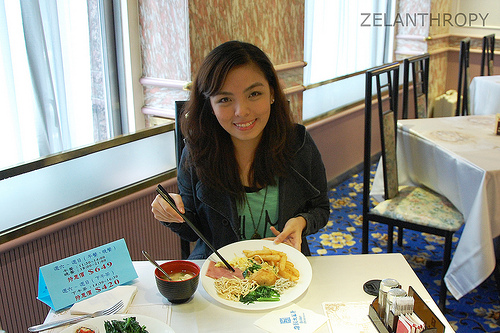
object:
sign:
[38, 238, 139, 310]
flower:
[319, 231, 356, 249]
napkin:
[250, 304, 325, 333]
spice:
[380, 280, 388, 306]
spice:
[384, 293, 391, 318]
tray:
[370, 281, 444, 331]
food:
[206, 261, 243, 279]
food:
[239, 285, 279, 302]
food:
[243, 244, 300, 282]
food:
[215, 278, 255, 300]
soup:
[156, 267, 197, 282]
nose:
[234, 100, 251, 117]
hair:
[180, 40, 293, 157]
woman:
[132, 31, 329, 264]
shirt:
[218, 172, 286, 242]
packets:
[394, 315, 411, 332]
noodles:
[251, 285, 255, 290]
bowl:
[154, 260, 199, 304]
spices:
[387, 297, 400, 326]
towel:
[70, 286, 136, 316]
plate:
[198, 237, 312, 312]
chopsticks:
[155, 184, 234, 273]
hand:
[151, 190, 186, 225]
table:
[466, 75, 500, 117]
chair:
[480, 36, 490, 76]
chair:
[454, 41, 474, 115]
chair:
[402, 52, 431, 119]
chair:
[364, 62, 466, 310]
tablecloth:
[398, 112, 498, 301]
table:
[396, 112, 499, 312]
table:
[38, 253, 458, 331]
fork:
[24, 300, 124, 331]